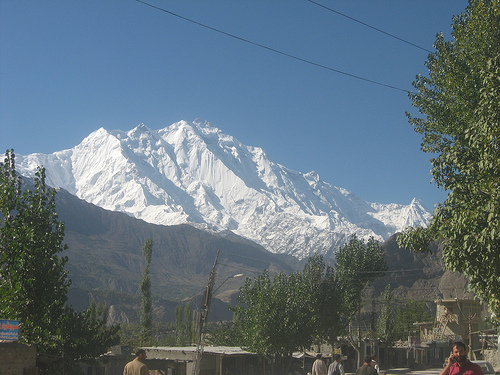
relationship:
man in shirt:
[440, 342, 477, 373] [445, 357, 482, 371]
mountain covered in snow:
[6, 116, 493, 295] [82, 147, 114, 163]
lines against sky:
[125, 0, 497, 102] [8, 10, 169, 105]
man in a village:
[122, 349, 149, 374] [1, 297, 498, 374]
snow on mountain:
[81, 126, 202, 218] [6, 116, 493, 295]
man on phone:
[437, 339, 490, 374] [447, 350, 460, 362]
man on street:
[118, 348, 152, 374] [409, 365, 449, 370]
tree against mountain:
[0, 146, 50, 341] [22, 181, 499, 362]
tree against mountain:
[21, 165, 86, 372] [22, 181, 499, 362]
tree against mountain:
[51, 302, 122, 373] [22, 181, 499, 362]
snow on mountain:
[93, 137, 121, 184] [1, 112, 432, 259]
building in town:
[379, 288, 494, 374] [2, 254, 499, 366]